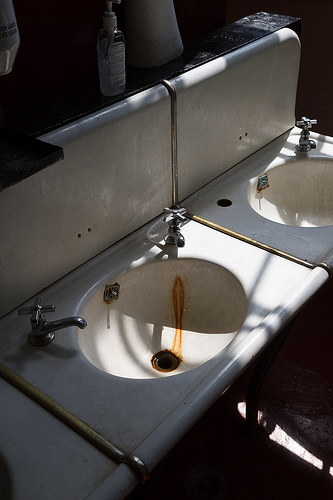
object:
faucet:
[16, 298, 88, 346]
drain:
[151, 349, 180, 373]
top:
[3, 9, 301, 189]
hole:
[86, 226, 93, 233]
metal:
[255, 175, 271, 191]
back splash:
[0, 27, 298, 313]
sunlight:
[235, 399, 332, 467]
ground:
[101, 276, 332, 498]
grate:
[104, 284, 120, 305]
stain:
[169, 272, 187, 366]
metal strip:
[160, 78, 185, 263]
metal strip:
[0, 362, 151, 489]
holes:
[238, 132, 242, 141]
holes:
[244, 128, 247, 138]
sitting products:
[0, 3, 20, 73]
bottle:
[95, 0, 125, 96]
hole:
[215, 196, 233, 208]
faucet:
[161, 205, 188, 249]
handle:
[294, 113, 314, 156]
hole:
[75, 233, 82, 239]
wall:
[0, 0, 280, 330]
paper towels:
[126, 0, 188, 73]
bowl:
[75, 255, 247, 384]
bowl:
[245, 154, 331, 227]